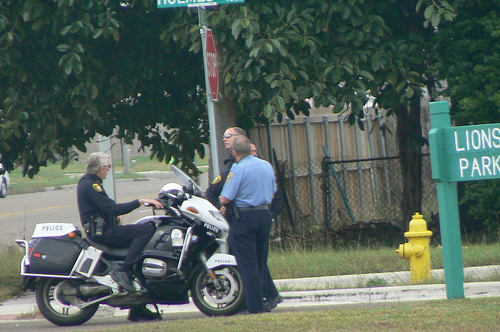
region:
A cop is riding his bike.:
[42, 107, 159, 329]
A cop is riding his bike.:
[88, 165, 172, 296]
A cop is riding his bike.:
[110, 140, 197, 300]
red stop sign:
[195, 29, 231, 102]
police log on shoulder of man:
[83, 179, 107, 199]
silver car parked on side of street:
[0, 154, 24, 201]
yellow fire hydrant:
[387, 208, 439, 288]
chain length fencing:
[321, 160, 397, 224]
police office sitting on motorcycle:
[24, 131, 206, 304]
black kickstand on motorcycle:
[146, 296, 168, 325]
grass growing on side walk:
[316, 273, 401, 290]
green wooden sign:
[427, 96, 498, 316]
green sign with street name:
[151, 0, 252, 13]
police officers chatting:
[9, 114, 286, 314]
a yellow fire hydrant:
[395, 207, 441, 301]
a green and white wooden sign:
[425, 100, 491, 302]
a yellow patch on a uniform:
[86, 180, 108, 192]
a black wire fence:
[336, 161, 397, 231]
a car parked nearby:
[1, 172, 11, 193]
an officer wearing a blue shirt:
[223, 136, 277, 309]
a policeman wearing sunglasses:
[220, 127, 234, 142]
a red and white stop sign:
[189, 25, 231, 124]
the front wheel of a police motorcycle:
[201, 271, 231, 305]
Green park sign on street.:
[425, 93, 499, 298]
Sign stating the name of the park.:
[431, 123, 499, 183]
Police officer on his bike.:
[14, 146, 251, 326]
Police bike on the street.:
[12, 165, 251, 321]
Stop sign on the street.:
[201, 22, 226, 104]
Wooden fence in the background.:
[232, 104, 499, 239]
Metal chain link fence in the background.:
[277, 155, 449, 248]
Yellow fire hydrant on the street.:
[396, 212, 441, 280]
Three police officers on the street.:
[201, 122, 283, 313]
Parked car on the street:
[1, 160, 12, 208]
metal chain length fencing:
[350, 157, 395, 211]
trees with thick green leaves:
[1, 1, 153, 142]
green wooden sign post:
[427, 100, 454, 301]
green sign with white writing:
[420, 105, 495, 296]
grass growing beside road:
[283, 247, 392, 273]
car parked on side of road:
[0, 156, 17, 196]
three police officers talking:
[21, 111, 296, 319]